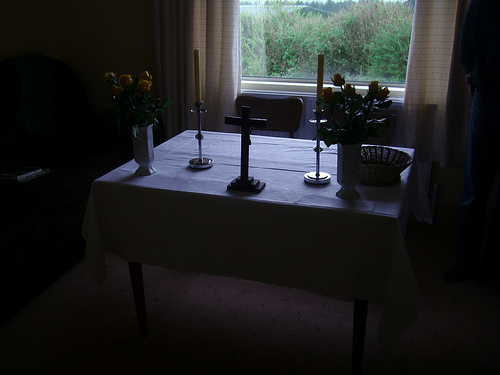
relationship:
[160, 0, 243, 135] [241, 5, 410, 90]
curtain on window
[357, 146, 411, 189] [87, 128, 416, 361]
basket on table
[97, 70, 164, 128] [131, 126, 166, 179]
flowers in a vase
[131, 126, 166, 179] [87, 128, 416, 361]
vase sitting on table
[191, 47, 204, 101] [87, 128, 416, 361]
candle on top of table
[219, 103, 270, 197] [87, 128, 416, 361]
crucifix on top of table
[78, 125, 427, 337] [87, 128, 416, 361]
table cloth on table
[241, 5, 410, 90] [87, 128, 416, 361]
window behind table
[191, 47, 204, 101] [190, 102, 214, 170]
candle inside a candle holder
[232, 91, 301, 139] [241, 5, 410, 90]
chair by window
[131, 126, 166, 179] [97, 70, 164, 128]
vase holds flowers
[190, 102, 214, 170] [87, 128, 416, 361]
candle holder on top of table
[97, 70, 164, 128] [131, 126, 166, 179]
flowers inside a vase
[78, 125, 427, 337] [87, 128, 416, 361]
table cloth on top of table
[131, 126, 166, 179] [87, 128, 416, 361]
vase on top of table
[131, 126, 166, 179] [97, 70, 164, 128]
vase holding flowers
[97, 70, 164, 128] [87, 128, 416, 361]
flowers on top of table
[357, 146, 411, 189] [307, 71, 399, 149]
basket near flowers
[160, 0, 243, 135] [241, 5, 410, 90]
curtain around window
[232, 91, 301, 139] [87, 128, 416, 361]
chair behind table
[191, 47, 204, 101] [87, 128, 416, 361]
candle sitting on top of table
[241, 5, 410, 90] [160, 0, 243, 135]
window behind curtain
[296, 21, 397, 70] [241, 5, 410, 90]
trees outside window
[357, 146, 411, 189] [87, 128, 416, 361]
basket sitting on top of table